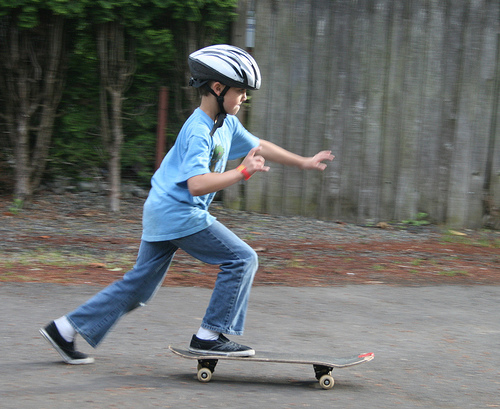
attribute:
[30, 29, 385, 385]
person — riding, little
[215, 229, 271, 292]
knee — bent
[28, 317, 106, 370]
shoe — black, slip on, white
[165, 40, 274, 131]
helmet — protection, white, black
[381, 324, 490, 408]
pavement — cement, gray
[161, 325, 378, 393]
skateboard — black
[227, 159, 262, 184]
wristband — red, plastic, orange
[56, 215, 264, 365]
jeans — blue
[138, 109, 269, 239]
shirt — blue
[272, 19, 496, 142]
fence — wooden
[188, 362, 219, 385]
wheel — grey, round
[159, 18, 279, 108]
helmet — silver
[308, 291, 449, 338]
ground — gray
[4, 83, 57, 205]
trunk — brown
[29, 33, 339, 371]
person — little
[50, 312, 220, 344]
socks — white